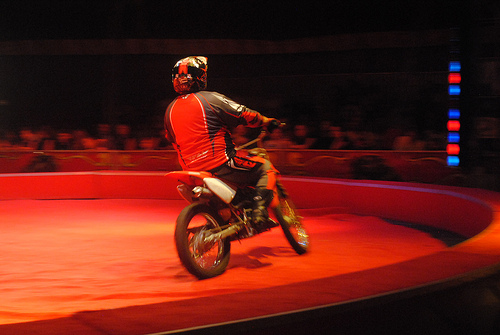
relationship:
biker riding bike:
[162, 56, 281, 228] [165, 123, 310, 279]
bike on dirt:
[165, 123, 310, 279] [0, 194, 452, 324]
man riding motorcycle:
[19, 125, 59, 183] [172, 147, 287, 268]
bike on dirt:
[165, 123, 310, 279] [4, 204, 179, 292]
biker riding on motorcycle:
[162, 56, 281, 228] [163, 117, 317, 272]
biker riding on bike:
[162, 56, 281, 228] [165, 123, 310, 279]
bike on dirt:
[165, 123, 310, 279] [55, 237, 122, 293]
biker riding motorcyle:
[162, 56, 281, 228] [168, 119, 310, 278]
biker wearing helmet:
[162, 56, 281, 228] [172, 56, 208, 94]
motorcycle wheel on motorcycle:
[174, 205, 231, 278] [93, 79, 395, 284]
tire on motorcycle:
[274, 194, 310, 254] [173, 122, 309, 277]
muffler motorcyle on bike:
[163, 164, 210, 215] [165, 123, 310, 279]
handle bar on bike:
[230, 128, 279, 154] [165, 123, 310, 279]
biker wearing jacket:
[162, 56, 281, 228] [166, 87, 259, 179]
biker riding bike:
[162, 56, 281, 228] [165, 146, 310, 284]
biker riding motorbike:
[162, 56, 281, 228] [116, 160, 297, 271]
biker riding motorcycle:
[162, 56, 281, 228] [173, 122, 309, 277]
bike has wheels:
[165, 123, 310, 279] [175, 186, 312, 280]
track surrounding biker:
[2, 177, 499, 329] [162, 56, 281, 228]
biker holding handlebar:
[162, 56, 281, 228] [224, 94, 289, 160]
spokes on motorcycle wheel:
[188, 219, 239, 296] [168, 175, 318, 275]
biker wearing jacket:
[162, 56, 281, 228] [163, 90, 268, 171]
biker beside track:
[162, 56, 281, 228] [0, 198, 460, 243]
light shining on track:
[445, 59, 457, 171] [8, 207, 146, 289]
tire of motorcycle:
[265, 187, 317, 254] [155, 111, 315, 284]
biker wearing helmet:
[150, 32, 302, 218] [162, 46, 212, 88]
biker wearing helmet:
[162, 56, 281, 228] [147, 42, 262, 78]